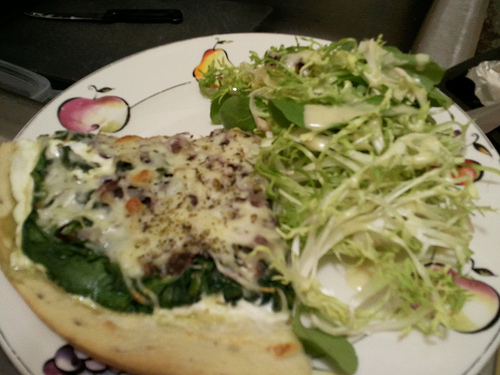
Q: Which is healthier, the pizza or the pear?
A: The pear is healthier than the pizza.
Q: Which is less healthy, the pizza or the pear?
A: The pizza is less healthy than the pear.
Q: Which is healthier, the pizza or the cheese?
A: The cheese is healthier than the pizza.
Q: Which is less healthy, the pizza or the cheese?
A: The pizza is less healthy than the cheese.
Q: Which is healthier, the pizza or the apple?
A: The apple is healthier than the pizza.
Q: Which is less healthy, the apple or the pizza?
A: The pizza is less healthy than the apple.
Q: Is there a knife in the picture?
A: Yes, there is a knife.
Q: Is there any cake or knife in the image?
A: Yes, there is a knife.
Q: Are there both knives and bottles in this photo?
A: No, there is a knife but no bottles.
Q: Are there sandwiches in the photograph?
A: No, there are no sandwiches.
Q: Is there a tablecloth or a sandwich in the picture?
A: No, there are no sandwiches or tablecloths.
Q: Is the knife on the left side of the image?
A: Yes, the knife is on the left of the image.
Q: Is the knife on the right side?
A: No, the knife is on the left of the image.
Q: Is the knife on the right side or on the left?
A: The knife is on the left of the image.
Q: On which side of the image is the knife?
A: The knife is on the left of the image.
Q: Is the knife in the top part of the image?
A: Yes, the knife is in the top of the image.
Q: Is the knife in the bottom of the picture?
A: No, the knife is in the top of the image.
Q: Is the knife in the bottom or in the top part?
A: The knife is in the top of the image.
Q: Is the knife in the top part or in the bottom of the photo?
A: The knife is in the top of the image.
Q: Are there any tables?
A: Yes, there is a table.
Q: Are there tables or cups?
A: Yes, there is a table.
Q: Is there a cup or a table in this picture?
A: Yes, there is a table.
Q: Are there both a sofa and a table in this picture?
A: No, there is a table but no sofas.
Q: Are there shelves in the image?
A: No, there are no shelves.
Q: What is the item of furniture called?
A: The piece of furniture is a table.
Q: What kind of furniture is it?
A: The piece of furniture is a table.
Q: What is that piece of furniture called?
A: This is a table.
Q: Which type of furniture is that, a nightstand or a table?
A: This is a table.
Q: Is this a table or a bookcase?
A: This is a table.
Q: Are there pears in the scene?
A: Yes, there is a pear.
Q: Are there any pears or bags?
A: Yes, there is a pear.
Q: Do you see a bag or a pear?
A: Yes, there is a pear.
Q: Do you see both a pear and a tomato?
A: No, there is a pear but no tomatoes.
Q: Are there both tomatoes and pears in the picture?
A: No, there is a pear but no tomatoes.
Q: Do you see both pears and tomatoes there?
A: No, there is a pear but no tomatoes.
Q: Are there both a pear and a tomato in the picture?
A: No, there is a pear but no tomatoes.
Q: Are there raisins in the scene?
A: No, there are no raisins.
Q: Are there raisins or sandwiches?
A: No, there are no raisins or sandwiches.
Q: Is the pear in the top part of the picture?
A: Yes, the pear is in the top of the image.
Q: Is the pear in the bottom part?
A: No, the pear is in the top of the image.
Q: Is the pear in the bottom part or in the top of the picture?
A: The pear is in the top of the image.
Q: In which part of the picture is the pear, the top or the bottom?
A: The pear is in the top of the image.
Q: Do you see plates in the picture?
A: Yes, there is a plate.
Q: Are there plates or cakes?
A: Yes, there is a plate.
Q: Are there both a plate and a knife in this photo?
A: Yes, there are both a plate and a knife.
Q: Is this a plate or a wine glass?
A: This is a plate.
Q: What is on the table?
A: The plate is on the table.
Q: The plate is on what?
A: The plate is on the table.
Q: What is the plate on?
A: The plate is on the table.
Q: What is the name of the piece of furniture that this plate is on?
A: The piece of furniture is a table.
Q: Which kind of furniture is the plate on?
A: The plate is on the table.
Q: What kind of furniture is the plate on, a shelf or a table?
A: The plate is on a table.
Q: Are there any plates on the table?
A: Yes, there is a plate on the table.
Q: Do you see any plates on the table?
A: Yes, there is a plate on the table.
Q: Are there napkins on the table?
A: No, there is a plate on the table.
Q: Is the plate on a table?
A: Yes, the plate is on a table.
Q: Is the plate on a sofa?
A: No, the plate is on a table.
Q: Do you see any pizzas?
A: Yes, there is a pizza.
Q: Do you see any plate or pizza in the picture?
A: Yes, there is a pizza.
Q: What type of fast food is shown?
A: The fast food is a pizza.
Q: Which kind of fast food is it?
A: The food is a pizza.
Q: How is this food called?
A: This is a pizza.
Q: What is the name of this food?
A: This is a pizza.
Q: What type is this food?
A: This is a pizza.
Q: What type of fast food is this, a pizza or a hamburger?
A: This is a pizza.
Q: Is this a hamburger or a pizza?
A: This is a pizza.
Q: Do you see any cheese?
A: Yes, there is cheese.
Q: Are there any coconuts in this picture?
A: No, there are no coconuts.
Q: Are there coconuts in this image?
A: No, there are no coconuts.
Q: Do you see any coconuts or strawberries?
A: No, there are no coconuts or strawberries.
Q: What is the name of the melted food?
A: The food is cheese.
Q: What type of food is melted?
A: The food is cheese.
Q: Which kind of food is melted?
A: The food is cheese.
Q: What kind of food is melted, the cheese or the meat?
A: The cheese is melted.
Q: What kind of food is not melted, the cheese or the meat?
A: The meat is not melted.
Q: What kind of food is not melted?
A: The food is meat.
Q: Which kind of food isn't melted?
A: The food is meat.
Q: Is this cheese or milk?
A: This is cheese.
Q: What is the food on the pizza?
A: The food is cheese.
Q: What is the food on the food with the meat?
A: The food is cheese.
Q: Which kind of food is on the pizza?
A: The food is cheese.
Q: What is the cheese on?
A: The cheese is on the pizza.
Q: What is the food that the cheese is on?
A: The food is a pizza.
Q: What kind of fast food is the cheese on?
A: The cheese is on the pizza.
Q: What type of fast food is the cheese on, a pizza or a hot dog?
A: The cheese is on a pizza.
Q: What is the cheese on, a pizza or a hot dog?
A: The cheese is on a pizza.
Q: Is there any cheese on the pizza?
A: Yes, there is cheese on the pizza.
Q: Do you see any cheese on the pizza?
A: Yes, there is cheese on the pizza.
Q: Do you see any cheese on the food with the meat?
A: Yes, there is cheese on the pizza.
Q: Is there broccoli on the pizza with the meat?
A: No, there is cheese on the pizza.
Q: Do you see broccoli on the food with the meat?
A: No, there is cheese on the pizza.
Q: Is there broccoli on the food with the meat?
A: No, there is cheese on the pizza.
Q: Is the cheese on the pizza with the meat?
A: Yes, the cheese is on the pizza.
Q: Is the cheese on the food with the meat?
A: Yes, the cheese is on the pizza.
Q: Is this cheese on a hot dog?
A: No, the cheese is on the pizza.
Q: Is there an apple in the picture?
A: Yes, there is an apple.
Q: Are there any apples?
A: Yes, there is an apple.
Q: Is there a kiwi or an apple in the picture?
A: Yes, there is an apple.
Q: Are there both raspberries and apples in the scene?
A: No, there is an apple but no raspberries.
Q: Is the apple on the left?
A: Yes, the apple is on the left of the image.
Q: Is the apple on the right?
A: No, the apple is on the left of the image.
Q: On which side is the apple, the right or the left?
A: The apple is on the left of the image.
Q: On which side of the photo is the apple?
A: The apple is on the left of the image.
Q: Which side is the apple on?
A: The apple is on the left of the image.